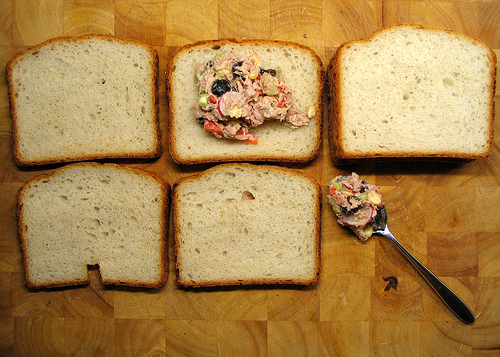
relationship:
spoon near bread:
[321, 172, 482, 329] [326, 21, 495, 161]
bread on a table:
[9, 44, 169, 152] [1, 2, 495, 354]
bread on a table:
[171, 160, 322, 290] [39, 293, 382, 342]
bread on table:
[326, 21, 495, 161] [1, 2, 495, 354]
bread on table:
[165, 37, 324, 164] [1, 2, 495, 354]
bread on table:
[9, 32, 169, 169] [1, 2, 495, 354]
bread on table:
[171, 160, 322, 290] [1, 2, 495, 354]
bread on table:
[17, 160, 172, 292] [1, 2, 495, 354]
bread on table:
[153, 38, 326, 168] [1, 2, 495, 354]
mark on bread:
[240, 188, 256, 200] [171, 160, 322, 290]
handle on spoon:
[383, 227, 475, 324] [321, 172, 482, 329]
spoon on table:
[321, 172, 482, 329] [1, 2, 495, 354]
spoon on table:
[321, 174, 482, 329] [344, 289, 396, 333]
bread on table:
[326, 31, 482, 190] [1, 2, 495, 354]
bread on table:
[326, 21, 495, 161] [4, 2, 340, 42]